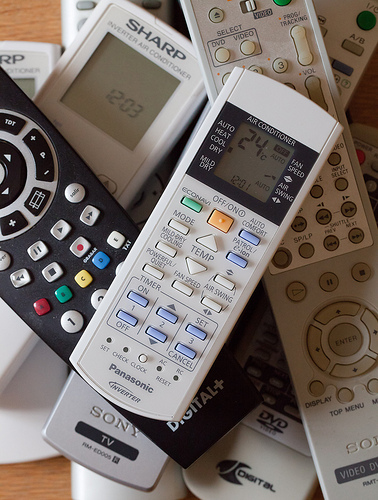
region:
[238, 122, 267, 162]
the number 24 on screen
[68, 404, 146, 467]
white Sony TV remote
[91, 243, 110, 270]
Blue button with letter D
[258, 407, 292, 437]
DVD in black on remote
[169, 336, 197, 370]
Blue cancel button on box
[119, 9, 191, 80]
White sharp air conditioner remote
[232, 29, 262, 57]
off white video button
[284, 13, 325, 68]
Programming button on remote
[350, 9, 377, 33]
Green power button on white remote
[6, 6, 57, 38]
Wooden table full of remotes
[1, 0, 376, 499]
pile of remote controls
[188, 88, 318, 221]
digital display on the remote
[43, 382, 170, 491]
Sony TV remote control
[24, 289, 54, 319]
red button on the remote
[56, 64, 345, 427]
Panasonic air conditioner remote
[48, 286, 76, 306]
green button on the remote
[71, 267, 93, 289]
yellow button on the remote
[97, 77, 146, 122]
12:03 displayed on the remote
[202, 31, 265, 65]
DVD and Video buttons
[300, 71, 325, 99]
button that controls the volume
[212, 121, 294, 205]
air conditioner remote control indicating 24C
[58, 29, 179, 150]
air conditioning remote control indicating 12:03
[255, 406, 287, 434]
industry-standard DVD logo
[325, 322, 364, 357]
"enter" button for remote control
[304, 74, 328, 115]
volume button for remote control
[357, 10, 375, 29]
on/off button for remote control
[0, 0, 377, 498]
wooden surface containing many remote controls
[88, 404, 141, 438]
SONY corporation logo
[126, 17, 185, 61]
Sharp corporate logo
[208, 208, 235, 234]
orange on/off button for remote control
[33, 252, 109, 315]
colored buttons on remote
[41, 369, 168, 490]
sony tv remote in pile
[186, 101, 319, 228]
air conditioner remote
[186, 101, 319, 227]
display screen for remote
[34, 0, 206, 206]
sharp air conditioner remote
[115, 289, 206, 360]
set of 6 blue buttons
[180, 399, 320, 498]
dvd digital remote control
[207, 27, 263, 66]
dvd and video select buttons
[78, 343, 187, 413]
logo of panasonic inverter on remote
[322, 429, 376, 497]
second sony logo on remote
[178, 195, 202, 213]
green button on remote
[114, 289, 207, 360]
group of blue buttons on remote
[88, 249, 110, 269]
blue button on remote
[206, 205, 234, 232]
orange button on remote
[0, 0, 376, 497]
group of many different remotes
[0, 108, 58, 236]
some of black buttons on remote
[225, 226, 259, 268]
two blue buttons on remote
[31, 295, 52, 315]
red button on remote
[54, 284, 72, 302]
green button on remote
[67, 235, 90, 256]
white button with red circle inside